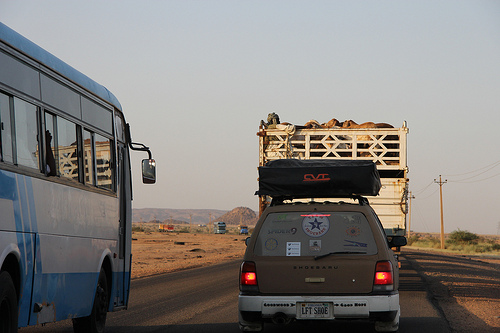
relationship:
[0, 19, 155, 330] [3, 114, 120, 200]
blue bus has windows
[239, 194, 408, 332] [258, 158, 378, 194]
car carrying bag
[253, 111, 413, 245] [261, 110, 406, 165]
truck carrying animals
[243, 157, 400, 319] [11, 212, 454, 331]
traffic traveling freeway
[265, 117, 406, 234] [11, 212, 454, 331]
traffic traveling freeway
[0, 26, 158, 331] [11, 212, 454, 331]
traffic traveling freeway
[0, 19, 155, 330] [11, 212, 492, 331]
blue bus are moving down freeway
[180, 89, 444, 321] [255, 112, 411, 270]
car following truck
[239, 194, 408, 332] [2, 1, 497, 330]
car traveling in weather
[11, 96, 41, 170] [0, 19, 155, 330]
window on blue bus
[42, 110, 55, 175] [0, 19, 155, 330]
window on blue bus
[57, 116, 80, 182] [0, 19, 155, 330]
window on blue bus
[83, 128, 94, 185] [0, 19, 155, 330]
window on blue bus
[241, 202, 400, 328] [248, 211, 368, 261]
back of windshield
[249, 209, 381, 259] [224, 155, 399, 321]
car window on car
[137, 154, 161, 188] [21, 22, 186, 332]
mirror on bus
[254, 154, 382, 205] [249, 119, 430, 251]
rack on truck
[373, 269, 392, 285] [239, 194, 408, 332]
brake lights on car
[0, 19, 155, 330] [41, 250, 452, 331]
blue bus on street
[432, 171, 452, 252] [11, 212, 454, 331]
pole beside freeway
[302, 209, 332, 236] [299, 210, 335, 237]
sticker with star